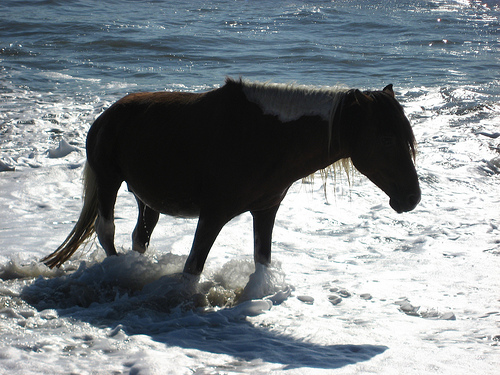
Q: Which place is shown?
A: It is a sea.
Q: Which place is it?
A: It is a sea.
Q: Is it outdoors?
A: Yes, it is outdoors.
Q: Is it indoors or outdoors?
A: It is outdoors.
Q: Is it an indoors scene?
A: No, it is outdoors.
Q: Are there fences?
A: No, there are no fences.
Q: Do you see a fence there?
A: No, there are no fences.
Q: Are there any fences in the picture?
A: No, there are no fences.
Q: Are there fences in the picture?
A: No, there are no fences.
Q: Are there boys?
A: No, there are no boys.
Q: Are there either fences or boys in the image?
A: No, there are no boys or fences.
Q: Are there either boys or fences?
A: No, there are no boys or fences.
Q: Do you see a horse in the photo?
A: Yes, there is a horse.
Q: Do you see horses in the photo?
A: Yes, there is a horse.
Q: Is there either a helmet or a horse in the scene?
A: Yes, there is a horse.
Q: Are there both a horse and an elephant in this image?
A: No, there is a horse but no elephants.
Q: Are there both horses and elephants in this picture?
A: No, there is a horse but no elephants.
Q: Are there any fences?
A: No, there are no fences.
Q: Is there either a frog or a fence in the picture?
A: No, there are no fences or frogs.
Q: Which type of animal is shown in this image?
A: The animal is a horse.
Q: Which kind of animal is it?
A: The animal is a horse.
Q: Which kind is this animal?
A: This is a horse.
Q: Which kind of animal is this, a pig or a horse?
A: This is a horse.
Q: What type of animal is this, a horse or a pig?
A: This is a horse.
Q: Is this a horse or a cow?
A: This is a horse.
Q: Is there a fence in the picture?
A: No, there are no fences.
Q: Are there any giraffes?
A: No, there are no giraffes.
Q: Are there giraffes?
A: No, there are no giraffes.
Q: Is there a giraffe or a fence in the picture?
A: No, there are no giraffes or fences.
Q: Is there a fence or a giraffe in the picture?
A: No, there are no giraffes or fences.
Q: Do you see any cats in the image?
A: No, there are no cats.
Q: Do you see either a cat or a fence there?
A: No, there are no cats or fences.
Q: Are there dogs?
A: No, there are no dogs.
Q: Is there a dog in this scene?
A: No, there are no dogs.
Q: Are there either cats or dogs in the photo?
A: No, there are no dogs or cats.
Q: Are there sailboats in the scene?
A: No, there are no sailboats.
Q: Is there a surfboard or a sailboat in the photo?
A: No, there are no sailboats or surfboards.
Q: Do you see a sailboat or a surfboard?
A: No, there are no sailboats or surfboards.